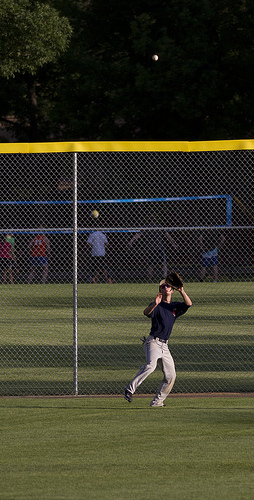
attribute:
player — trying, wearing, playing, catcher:
[95, 246, 233, 388]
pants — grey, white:
[146, 333, 186, 408]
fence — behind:
[39, 180, 195, 353]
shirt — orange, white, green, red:
[23, 235, 46, 278]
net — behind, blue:
[120, 174, 235, 228]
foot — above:
[112, 375, 164, 436]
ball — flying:
[113, 22, 168, 73]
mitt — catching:
[164, 271, 197, 303]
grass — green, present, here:
[58, 404, 220, 433]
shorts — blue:
[28, 256, 56, 277]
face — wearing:
[146, 274, 182, 303]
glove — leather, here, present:
[159, 246, 209, 303]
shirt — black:
[148, 278, 189, 357]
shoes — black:
[123, 384, 216, 459]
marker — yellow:
[69, 116, 191, 192]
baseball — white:
[142, 49, 221, 86]